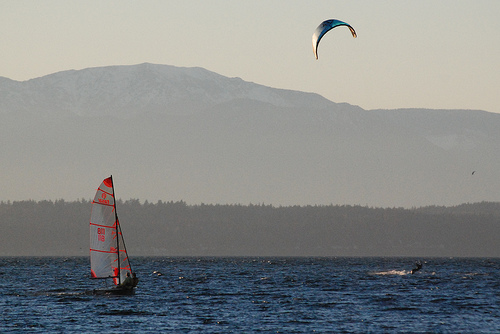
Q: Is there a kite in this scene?
A: Yes, there is a kite.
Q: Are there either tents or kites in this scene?
A: Yes, there is a kite.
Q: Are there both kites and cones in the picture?
A: No, there is a kite but no cones.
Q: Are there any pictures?
A: No, there are no pictures.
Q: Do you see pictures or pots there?
A: No, there are no pictures or pots.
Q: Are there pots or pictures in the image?
A: No, there are no pictures or pots.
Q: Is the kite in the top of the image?
A: Yes, the kite is in the top of the image.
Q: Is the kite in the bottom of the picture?
A: No, the kite is in the top of the image.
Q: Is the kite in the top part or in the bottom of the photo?
A: The kite is in the top of the image.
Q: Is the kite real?
A: Yes, the kite is real.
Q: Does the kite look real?
A: Yes, the kite is real.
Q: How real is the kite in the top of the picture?
A: The kite is real.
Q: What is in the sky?
A: The kite is in the sky.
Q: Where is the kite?
A: The kite is in the sky.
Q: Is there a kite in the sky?
A: Yes, there is a kite in the sky.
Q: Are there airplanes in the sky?
A: No, there is a kite in the sky.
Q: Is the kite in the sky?
A: Yes, the kite is in the sky.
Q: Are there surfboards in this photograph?
A: No, there are no surfboards.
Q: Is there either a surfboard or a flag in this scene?
A: No, there are no surfboards or flags.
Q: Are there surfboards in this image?
A: No, there are no surfboards.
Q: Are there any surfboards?
A: No, there are no surfboards.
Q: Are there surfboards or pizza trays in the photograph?
A: No, there are no surfboards or pizza trays.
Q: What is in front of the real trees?
A: The water is in front of the trees.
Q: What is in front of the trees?
A: The water is in front of the trees.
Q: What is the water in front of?
A: The water is in front of the trees.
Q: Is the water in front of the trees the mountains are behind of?
A: Yes, the water is in front of the trees.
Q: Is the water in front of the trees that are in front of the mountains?
A: Yes, the water is in front of the trees.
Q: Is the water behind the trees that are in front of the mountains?
A: No, the water is in front of the trees.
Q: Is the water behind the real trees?
A: No, the water is in front of the trees.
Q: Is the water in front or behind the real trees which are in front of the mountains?
A: The water is in front of the trees.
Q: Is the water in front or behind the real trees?
A: The water is in front of the trees.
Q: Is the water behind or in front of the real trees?
A: The water is in front of the trees.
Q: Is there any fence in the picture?
A: No, there are no fences.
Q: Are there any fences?
A: No, there are no fences.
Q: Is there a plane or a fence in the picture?
A: No, there are no fences or airplanes.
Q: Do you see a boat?
A: Yes, there is a boat.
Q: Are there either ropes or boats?
A: Yes, there is a boat.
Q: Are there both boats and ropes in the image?
A: No, there is a boat but no ropes.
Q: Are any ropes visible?
A: No, there are no ropes.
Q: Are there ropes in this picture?
A: No, there are no ropes.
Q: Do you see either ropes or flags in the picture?
A: No, there are no ropes or flags.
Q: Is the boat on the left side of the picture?
A: Yes, the boat is on the left of the image.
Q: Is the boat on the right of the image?
A: No, the boat is on the left of the image.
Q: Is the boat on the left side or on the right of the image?
A: The boat is on the left of the image.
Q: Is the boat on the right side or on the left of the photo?
A: The boat is on the left of the image.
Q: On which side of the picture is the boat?
A: The boat is on the left of the image.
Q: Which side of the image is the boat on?
A: The boat is on the left of the image.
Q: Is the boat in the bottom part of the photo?
A: Yes, the boat is in the bottom of the image.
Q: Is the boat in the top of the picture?
A: No, the boat is in the bottom of the image.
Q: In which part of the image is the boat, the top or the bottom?
A: The boat is in the bottom of the image.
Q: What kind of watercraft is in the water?
A: The watercraft is a boat.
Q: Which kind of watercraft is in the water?
A: The watercraft is a boat.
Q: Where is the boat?
A: The boat is in the water.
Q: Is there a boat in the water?
A: Yes, there is a boat in the water.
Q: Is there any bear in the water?
A: No, there is a boat in the water.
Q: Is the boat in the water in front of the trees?
A: Yes, the boat is in the water.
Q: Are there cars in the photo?
A: No, there are no cars.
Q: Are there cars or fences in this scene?
A: No, there are no cars or fences.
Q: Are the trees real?
A: Yes, the trees are real.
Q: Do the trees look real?
A: Yes, the trees are real.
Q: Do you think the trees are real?
A: Yes, the trees are real.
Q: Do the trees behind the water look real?
A: Yes, the trees are real.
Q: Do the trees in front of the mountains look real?
A: Yes, the trees are real.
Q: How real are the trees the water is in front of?
A: The trees are real.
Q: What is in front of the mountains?
A: The trees are in front of the mountains.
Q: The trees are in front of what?
A: The trees are in front of the mountains.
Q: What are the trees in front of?
A: The trees are in front of the mountains.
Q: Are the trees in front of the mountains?
A: Yes, the trees are in front of the mountains.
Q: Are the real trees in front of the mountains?
A: Yes, the trees are in front of the mountains.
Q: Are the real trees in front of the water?
A: No, the trees are behind the water.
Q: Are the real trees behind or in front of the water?
A: The trees are behind the water.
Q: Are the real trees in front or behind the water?
A: The trees are behind the water.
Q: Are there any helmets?
A: No, there are no helmets.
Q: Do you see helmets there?
A: No, there are no helmets.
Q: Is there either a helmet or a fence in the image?
A: No, there are no helmets or fences.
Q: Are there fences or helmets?
A: No, there are no helmets or fences.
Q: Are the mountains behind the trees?
A: Yes, the mountains are behind the trees.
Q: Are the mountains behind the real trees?
A: Yes, the mountains are behind the trees.